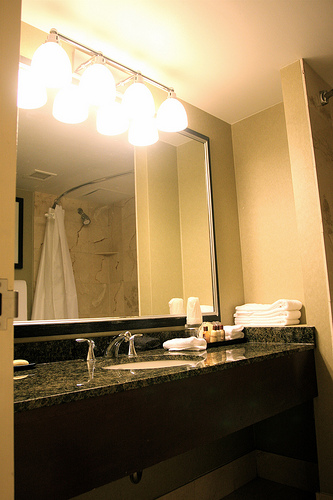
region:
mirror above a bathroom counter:
[20, 93, 276, 400]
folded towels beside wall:
[226, 292, 305, 338]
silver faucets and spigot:
[70, 318, 142, 368]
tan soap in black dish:
[10, 348, 41, 372]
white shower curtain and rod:
[24, 180, 121, 317]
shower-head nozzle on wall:
[69, 200, 97, 230]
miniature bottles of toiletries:
[197, 319, 228, 343]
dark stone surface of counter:
[36, 347, 236, 391]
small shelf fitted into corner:
[93, 237, 117, 265]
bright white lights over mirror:
[34, 30, 188, 151]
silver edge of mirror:
[189, 129, 225, 152]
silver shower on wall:
[75, 199, 110, 235]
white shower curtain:
[28, 197, 126, 276]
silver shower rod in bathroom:
[43, 187, 120, 209]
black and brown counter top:
[45, 366, 85, 386]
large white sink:
[110, 349, 205, 384]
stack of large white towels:
[229, 294, 319, 319]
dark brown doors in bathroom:
[71, 402, 314, 426]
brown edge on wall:
[18, 194, 35, 230]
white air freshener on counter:
[173, 289, 211, 334]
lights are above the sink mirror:
[28, 25, 189, 152]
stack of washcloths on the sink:
[231, 294, 300, 332]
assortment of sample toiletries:
[202, 319, 227, 345]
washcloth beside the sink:
[161, 328, 203, 358]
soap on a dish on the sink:
[12, 355, 32, 371]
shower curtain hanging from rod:
[33, 198, 83, 325]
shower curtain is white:
[29, 201, 82, 321]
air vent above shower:
[22, 168, 51, 187]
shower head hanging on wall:
[74, 205, 90, 234]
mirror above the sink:
[12, 113, 223, 331]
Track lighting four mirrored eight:
[20, 25, 206, 156]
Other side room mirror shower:
[38, 165, 137, 313]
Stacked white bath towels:
[227, 299, 311, 334]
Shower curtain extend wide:
[32, 178, 81, 253]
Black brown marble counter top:
[22, 344, 82, 400]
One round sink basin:
[99, 355, 213, 392]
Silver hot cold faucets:
[76, 331, 145, 366]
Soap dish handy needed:
[9, 349, 44, 376]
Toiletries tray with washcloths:
[199, 321, 230, 346]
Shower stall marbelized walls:
[89, 200, 134, 316]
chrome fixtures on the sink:
[71, 331, 147, 360]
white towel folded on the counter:
[232, 299, 296, 325]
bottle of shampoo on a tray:
[202, 325, 224, 343]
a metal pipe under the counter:
[126, 470, 148, 480]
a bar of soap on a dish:
[15, 358, 33, 367]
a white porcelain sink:
[112, 356, 186, 368]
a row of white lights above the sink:
[36, 62, 185, 140]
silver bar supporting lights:
[56, 30, 101, 48]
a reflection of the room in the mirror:
[28, 165, 131, 313]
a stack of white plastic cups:
[187, 295, 199, 328]